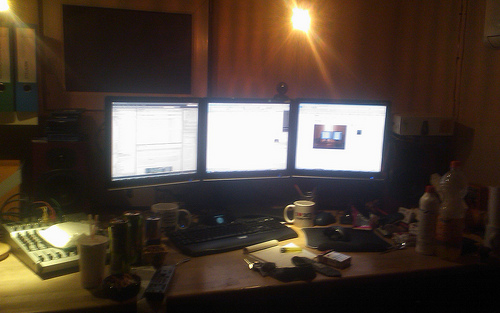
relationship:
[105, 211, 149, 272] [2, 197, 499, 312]
cans on desk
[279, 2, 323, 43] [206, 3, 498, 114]
light on wall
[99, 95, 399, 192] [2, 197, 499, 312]
monitors on desk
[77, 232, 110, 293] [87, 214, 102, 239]
cup with straw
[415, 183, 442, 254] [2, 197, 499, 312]
spray can on desk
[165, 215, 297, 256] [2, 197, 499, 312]
keyboard on top of desk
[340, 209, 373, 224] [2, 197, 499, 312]
sunglasses on top of desk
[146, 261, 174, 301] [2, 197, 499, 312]
remote control on top of desk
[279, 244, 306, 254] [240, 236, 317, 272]
lighter on top of writing pad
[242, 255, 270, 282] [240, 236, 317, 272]
keys on writing pad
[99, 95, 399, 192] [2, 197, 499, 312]
monitors on top of desk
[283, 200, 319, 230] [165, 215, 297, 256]
mug behind keyboard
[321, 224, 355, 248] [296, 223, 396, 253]
mouse on pad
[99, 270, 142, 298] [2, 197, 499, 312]
ashtray on top of desk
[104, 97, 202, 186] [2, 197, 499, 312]
monitor on top of desk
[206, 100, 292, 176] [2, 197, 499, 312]
monitor on top of desk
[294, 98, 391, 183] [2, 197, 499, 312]
monitor on top of desk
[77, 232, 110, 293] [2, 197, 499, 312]
cup on desk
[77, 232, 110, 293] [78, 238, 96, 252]
cup for coffee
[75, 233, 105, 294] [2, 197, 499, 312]
mixer on desk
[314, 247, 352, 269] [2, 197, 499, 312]
cigarrettes on desk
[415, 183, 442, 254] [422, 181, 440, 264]
bottle for cleaning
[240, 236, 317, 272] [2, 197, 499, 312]
notepad on desk